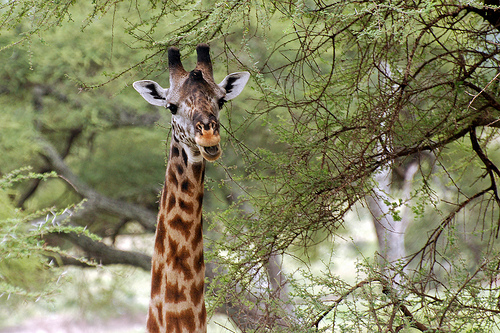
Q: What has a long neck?
A: Giraffe.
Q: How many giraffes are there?
A: One.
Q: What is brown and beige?
A: A giraffe.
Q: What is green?
A: Trees.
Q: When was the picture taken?
A: Daytime.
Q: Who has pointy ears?
A: The giraffe.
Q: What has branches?
A: Trees.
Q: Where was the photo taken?
A: The zoo.